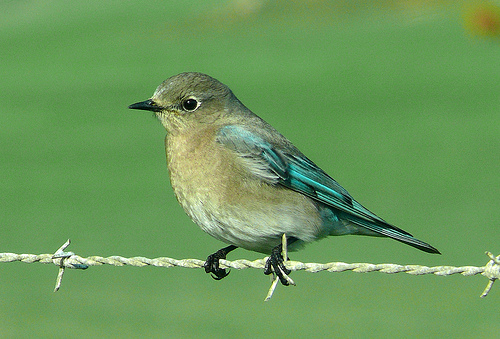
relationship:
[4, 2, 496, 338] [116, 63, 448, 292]
grass behind bird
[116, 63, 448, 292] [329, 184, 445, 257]
bird has tail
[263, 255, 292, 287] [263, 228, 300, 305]
foot on barb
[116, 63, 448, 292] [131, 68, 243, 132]
bird has head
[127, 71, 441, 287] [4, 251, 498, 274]
bird on wire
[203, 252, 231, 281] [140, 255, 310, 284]
foot hods wire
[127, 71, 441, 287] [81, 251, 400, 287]
bird on wire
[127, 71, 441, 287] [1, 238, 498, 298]
bird grasp wire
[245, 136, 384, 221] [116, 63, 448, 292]
feather on bird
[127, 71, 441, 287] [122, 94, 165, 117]
bird has beak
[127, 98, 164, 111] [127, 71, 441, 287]
beak on bird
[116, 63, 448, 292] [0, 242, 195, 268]
bird on wire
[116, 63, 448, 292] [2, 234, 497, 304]
bird on a barbed-wire fence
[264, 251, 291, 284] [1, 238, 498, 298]
foot on a wire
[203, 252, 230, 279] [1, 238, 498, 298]
foot on a wire